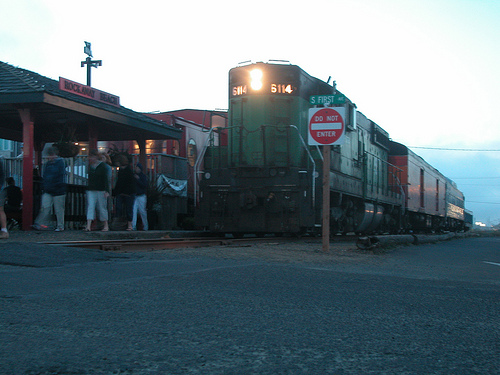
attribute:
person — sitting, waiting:
[4, 174, 26, 234]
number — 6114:
[230, 81, 249, 98]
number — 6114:
[268, 81, 294, 96]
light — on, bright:
[243, 65, 269, 96]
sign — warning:
[306, 104, 348, 146]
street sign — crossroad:
[306, 92, 345, 257]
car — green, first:
[188, 57, 407, 255]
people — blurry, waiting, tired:
[3, 139, 156, 236]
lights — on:
[245, 63, 269, 94]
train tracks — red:
[34, 229, 289, 257]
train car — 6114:
[196, 56, 407, 259]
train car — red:
[385, 137, 451, 237]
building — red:
[131, 107, 228, 160]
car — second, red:
[387, 138, 450, 236]